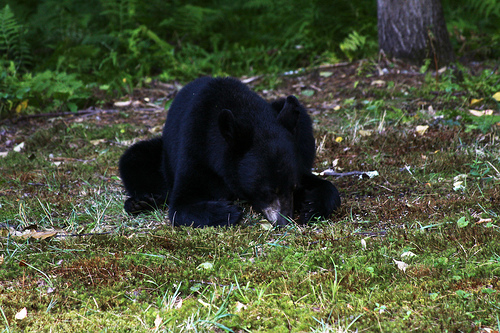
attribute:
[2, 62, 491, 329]
grass — patch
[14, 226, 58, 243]
light leaf — brown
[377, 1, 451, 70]
tree — base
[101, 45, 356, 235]
bear — black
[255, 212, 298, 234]
nose — bear's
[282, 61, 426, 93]
dirt — patch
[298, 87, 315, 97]
leaves — fallen 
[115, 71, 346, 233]
bear — black,  behind, laying down, sleeping, left hind, asleep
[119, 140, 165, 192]
leg — black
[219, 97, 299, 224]
head — black bear's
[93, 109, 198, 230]
leg — black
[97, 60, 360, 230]
bear — laying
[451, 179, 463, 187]
leaf — light brown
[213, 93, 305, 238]
head — black 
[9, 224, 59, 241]
leaf — light brown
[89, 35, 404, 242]
bear — black, laying down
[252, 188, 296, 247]
snout — brown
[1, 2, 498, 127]
foliage — green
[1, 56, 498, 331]
weeds — patch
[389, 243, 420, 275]
leaf — light brown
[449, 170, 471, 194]
leaf — light brown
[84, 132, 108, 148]
leaf — light brown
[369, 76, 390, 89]
leaf — light brown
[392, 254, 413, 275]
leaf — light brown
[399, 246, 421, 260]
leaf — light brown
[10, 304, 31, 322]
leaf — light brown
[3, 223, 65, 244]
leaf — light brown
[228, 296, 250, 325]
leaf — light brown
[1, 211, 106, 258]
branch — fallen